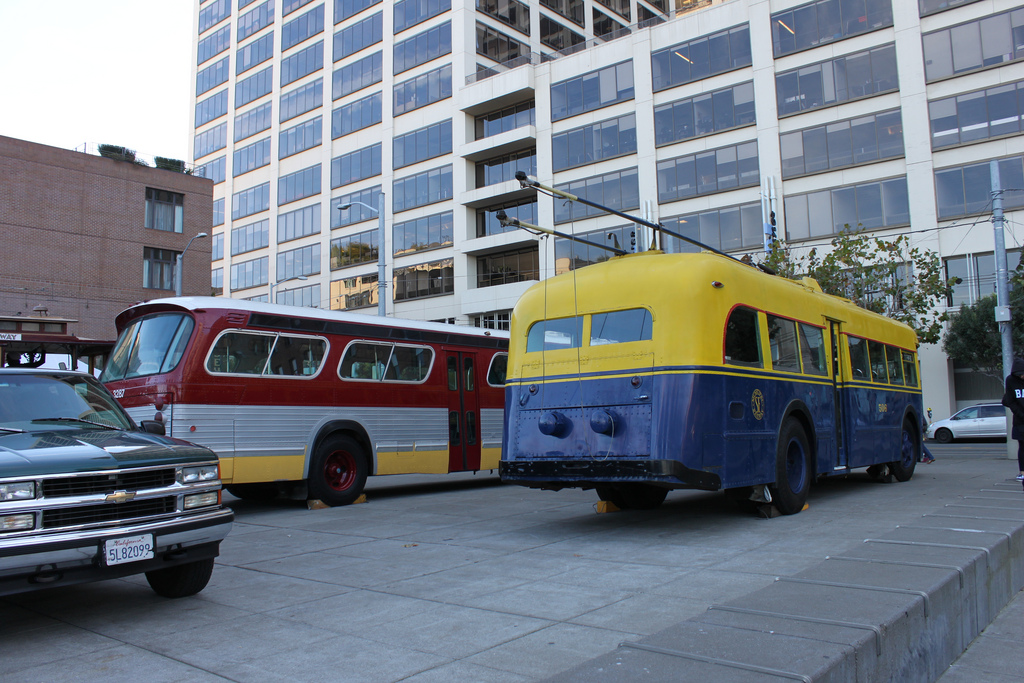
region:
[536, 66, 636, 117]
a window on a building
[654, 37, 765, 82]
a window on a building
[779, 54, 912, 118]
a window on a building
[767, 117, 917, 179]
a window on a building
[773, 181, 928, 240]
a window on a building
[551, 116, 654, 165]
a window on a building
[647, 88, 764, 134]
a window on a building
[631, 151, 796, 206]
a window on a building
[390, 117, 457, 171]
a window on a building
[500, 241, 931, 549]
blue and yellow bus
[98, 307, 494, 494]
red silver and yellow bus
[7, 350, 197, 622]
green truck is stopped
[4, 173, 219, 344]
tall red brick building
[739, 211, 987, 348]
green tree behind bus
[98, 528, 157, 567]
red and blue license plate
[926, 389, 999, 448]
grey van behind bus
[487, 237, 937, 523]
blue and white bus on road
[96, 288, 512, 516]
red,white and yellow bus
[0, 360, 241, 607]
SUV parked in front of bus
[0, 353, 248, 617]
SUV with license plate written in blue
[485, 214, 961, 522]
Green tree in front of yellow and blue bus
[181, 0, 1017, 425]
building with lots of glass window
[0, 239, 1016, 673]
buses on top of gray concrete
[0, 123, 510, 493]
brown building in back of red and white bus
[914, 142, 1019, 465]
pole on side of silver car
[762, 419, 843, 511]
tire on a bus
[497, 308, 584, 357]
window on a bus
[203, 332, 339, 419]
window on a bus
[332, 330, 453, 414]
window on a bus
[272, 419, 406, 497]
tire on a bus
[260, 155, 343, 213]
window on a building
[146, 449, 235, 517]
light on a truck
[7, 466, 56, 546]
light on a truck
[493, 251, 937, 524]
A blue and yellow bus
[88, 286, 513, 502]
A red, yellow, and silver bus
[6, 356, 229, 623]
A parked SUV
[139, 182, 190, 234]
A window of the building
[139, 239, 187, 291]
A window of the building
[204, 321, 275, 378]
A window of the bus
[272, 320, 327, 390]
A window of the bus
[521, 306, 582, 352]
A window of the bus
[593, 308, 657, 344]
A window of the bus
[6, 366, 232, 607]
truck parked beside the buses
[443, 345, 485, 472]
red door on the bus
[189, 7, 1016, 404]
large white building in front of the buses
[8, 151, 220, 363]
brick building next to the buses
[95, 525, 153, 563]
front license plate on the truck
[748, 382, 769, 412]
yellow logo on the blue and yellow bus